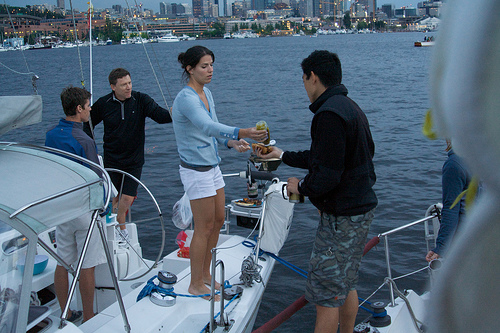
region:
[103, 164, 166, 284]
the sailboats steering wheel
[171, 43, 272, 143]
a girl squeezing a ketchup bottle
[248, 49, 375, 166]
a man holding a hotdog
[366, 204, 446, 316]
a sailboats stainless safety rail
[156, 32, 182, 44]
a white cruising yacht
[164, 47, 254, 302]
woman wearing white shorts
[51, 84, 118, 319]
man wearing gray and blue jacket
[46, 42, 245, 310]
three people standing on a boat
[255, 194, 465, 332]
railing around boat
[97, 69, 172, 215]
man wearing black shorts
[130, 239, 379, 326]
blue ropes on the boats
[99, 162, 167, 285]
steering wheel on the boat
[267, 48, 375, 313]
man wearing camoflauge shorts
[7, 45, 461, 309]
river the boats are in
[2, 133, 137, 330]
shelter on the boat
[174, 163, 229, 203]
white shorts the woman is wearing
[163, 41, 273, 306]
a woman standing on the boat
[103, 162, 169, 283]
a steering wheel of the boat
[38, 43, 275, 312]
people standing on the boat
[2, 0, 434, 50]
a city in the background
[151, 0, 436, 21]
buildings in the background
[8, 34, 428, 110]
body of water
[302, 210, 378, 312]
shorts the guy is wearing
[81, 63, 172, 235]
a person wearing black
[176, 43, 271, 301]
A woman squirting mustard.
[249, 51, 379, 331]
A man holding a hot dog.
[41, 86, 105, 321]
A young man looking at the water.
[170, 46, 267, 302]
A young woman with a pony tail.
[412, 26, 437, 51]
A boat in the distance, sailing in the water.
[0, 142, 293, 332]
A boat parked at the harbor.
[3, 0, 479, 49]
A city skyline overlooking the harbor.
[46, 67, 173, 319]
Two men engaging in conversation.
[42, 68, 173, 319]
Two men standing on a boat.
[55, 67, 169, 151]
Men talking on a boat.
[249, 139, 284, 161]
A hot dog in a hand.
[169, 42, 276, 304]
A woman putting condiment on a hotdog.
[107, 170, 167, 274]
Steering wheel of a boat.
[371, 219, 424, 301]
Railing on a boat.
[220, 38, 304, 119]
A choppy lake.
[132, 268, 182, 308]
Rope winder on the boat.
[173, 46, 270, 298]
woman is standing on a boat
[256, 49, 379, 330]
man is standing on a boat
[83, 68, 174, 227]
man is standing on a boat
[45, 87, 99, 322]
young kid is standing on a boat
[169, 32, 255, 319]
woman wearing blue sweater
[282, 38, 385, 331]
man wearing black sweater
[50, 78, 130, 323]
man wearing white shorts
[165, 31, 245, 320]
woman standing on boat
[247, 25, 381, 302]
man holding hot dog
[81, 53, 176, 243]
man wearing black shortd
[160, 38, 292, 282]
woman squeezing ketchup on man's hot dog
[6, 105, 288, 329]
small white boat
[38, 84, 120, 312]
man wearing blue and gray jacket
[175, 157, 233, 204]
A pair of white shorts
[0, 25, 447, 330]
The water appears to be calm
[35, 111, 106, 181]
A blue and gray jacket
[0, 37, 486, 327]
People standing on boats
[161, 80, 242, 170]
A blue long sleeved sweater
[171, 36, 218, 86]
Woman's brown hair in a bun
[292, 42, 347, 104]
A guy has black hair